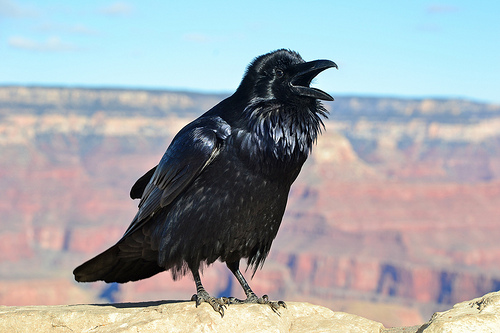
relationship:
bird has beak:
[71, 44, 344, 315] [287, 60, 339, 102]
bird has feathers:
[71, 44, 344, 315] [168, 101, 329, 281]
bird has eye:
[71, 44, 344, 315] [273, 67, 287, 78]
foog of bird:
[190, 290, 231, 316] [71, 44, 344, 315]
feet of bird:
[188, 285, 288, 316] [71, 44, 344, 315]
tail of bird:
[70, 227, 164, 291] [71, 44, 344, 315]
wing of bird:
[119, 114, 224, 242] [71, 44, 344, 315]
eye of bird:
[273, 67, 287, 78] [71, 44, 344, 315]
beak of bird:
[287, 60, 339, 102] [71, 44, 344, 315]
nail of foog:
[216, 304, 225, 314] [190, 290, 231, 316]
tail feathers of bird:
[71, 236, 158, 286] [71, 44, 344, 315]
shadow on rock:
[89, 294, 182, 314] [0, 290, 498, 331]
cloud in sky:
[1, 5, 99, 55] [2, 3, 500, 101]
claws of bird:
[198, 290, 291, 320] [71, 44, 344, 315]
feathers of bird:
[76, 100, 321, 285] [71, 44, 344, 315]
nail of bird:
[216, 304, 225, 314] [71, 44, 344, 315]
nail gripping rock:
[216, 304, 225, 314] [0, 298, 390, 331]